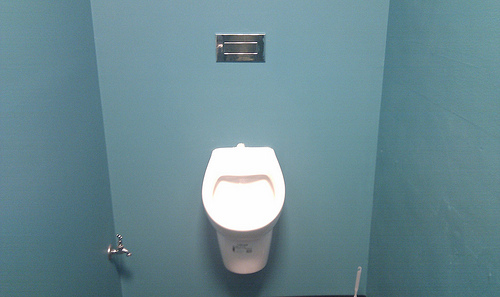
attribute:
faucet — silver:
[103, 229, 134, 261]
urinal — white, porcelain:
[192, 134, 291, 278]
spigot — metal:
[115, 234, 132, 259]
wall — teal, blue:
[306, 20, 378, 110]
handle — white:
[354, 264, 365, 278]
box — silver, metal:
[215, 30, 266, 66]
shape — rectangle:
[223, 41, 257, 54]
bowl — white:
[217, 183, 269, 212]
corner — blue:
[374, 42, 391, 80]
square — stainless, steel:
[220, 39, 260, 61]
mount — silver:
[223, 33, 262, 57]